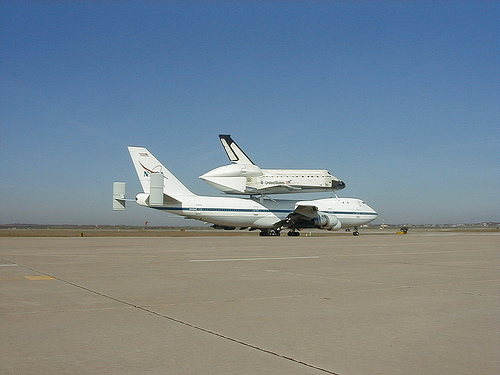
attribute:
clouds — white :
[348, 121, 491, 186]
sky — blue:
[12, 7, 490, 230]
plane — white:
[110, 142, 380, 238]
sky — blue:
[0, 0, 498, 131]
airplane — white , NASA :
[108, 136, 378, 238]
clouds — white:
[382, 98, 473, 198]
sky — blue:
[2, 0, 498, 217]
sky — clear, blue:
[11, 10, 487, 124]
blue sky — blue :
[1, 0, 498, 227]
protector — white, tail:
[198, 160, 238, 194]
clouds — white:
[283, 84, 403, 142]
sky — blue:
[395, 26, 471, 129]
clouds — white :
[25, 125, 105, 213]